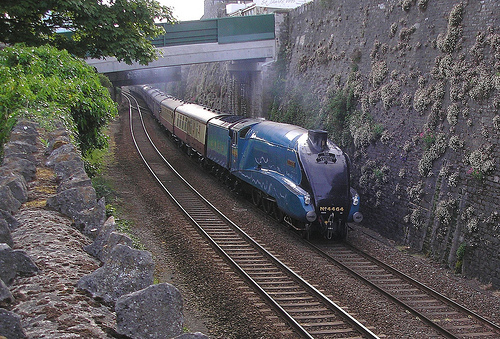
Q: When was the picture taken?
A: Daytime.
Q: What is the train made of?
A: Metal.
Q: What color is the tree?
A: Green.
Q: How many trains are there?
A: One.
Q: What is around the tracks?
A: Gravel.